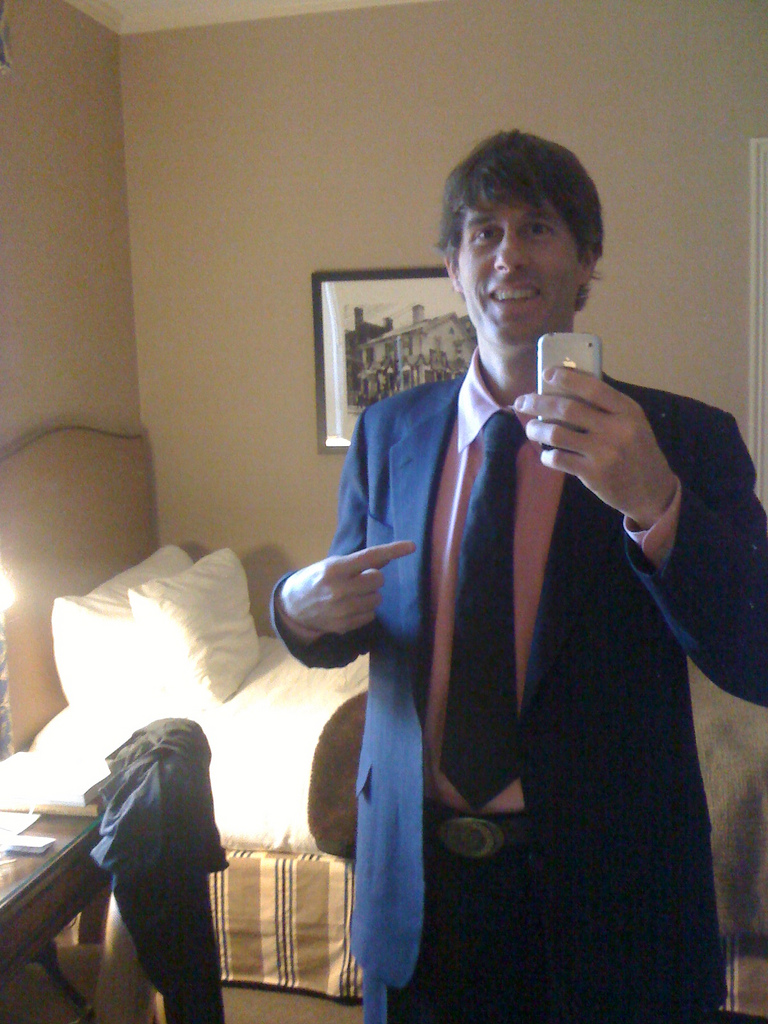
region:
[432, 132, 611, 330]
a man with black hair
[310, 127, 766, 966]
a man wearing a blue suit jacket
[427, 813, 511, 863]
a metal belt buckle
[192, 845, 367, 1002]
the dust ruffle on a bed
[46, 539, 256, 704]
two pillows with white covers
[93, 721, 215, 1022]
clothing draped over the back of a chair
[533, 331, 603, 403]
a white colored smartphone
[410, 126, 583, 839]
a man wearing a pink shirt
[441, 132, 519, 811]
a man wearing a neck tie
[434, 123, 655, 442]
a man holding a cell phone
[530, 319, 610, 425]
a white cell phone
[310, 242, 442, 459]
a picture hanging on a wall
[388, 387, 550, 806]
a man wearing a pink shirt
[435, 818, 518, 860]
a man wearing belt buckle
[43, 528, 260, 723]
two pillows on a bed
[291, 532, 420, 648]
a man pointing his finger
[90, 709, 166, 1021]
a piece of clothing on a chair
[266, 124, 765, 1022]
man holding an iphone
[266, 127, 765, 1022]
man in a blue suit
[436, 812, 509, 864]
brass belt buckle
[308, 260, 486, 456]
picture on the wall behind the man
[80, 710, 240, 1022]
piece of clothing on the back of a chair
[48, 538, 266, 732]
white pillows on the bed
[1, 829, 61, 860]
folded piece of paper on the table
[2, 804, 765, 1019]
brown and blue bed skirt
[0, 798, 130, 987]
brown wooden desk with glass top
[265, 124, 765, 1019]
guy wearing a pink shirt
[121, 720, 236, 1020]
the jacket is on the chair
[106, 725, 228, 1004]
the jacket is black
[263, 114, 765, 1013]
a man taking a selfie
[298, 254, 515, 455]
picture on the wall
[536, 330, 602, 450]
the apple device is silver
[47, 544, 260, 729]
the pillows are white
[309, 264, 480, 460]
the frame is black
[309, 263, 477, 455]
the picture in the frame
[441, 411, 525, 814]
the tie is long and dark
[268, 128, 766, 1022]
the man is wearing a suit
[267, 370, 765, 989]
the suit jacket is dark colored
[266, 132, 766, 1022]
the man wearing a tie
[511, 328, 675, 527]
the hand holding the device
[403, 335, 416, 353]
A window on a building.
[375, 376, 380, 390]
A window on a building.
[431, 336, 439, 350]
A window on a building.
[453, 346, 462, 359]
A window on a building.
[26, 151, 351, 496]
the wall is light brown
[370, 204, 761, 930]
the man is smiling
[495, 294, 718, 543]
the man is holding a phone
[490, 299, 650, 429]
the phone is white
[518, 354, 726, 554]
the hand is holding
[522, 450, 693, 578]
the sleeves are pink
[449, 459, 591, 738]
the shirt is pink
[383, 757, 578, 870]
the buckle is metal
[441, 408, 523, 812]
the tie is long and black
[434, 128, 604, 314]
the hair is brown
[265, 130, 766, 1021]
the man is holding up a phone